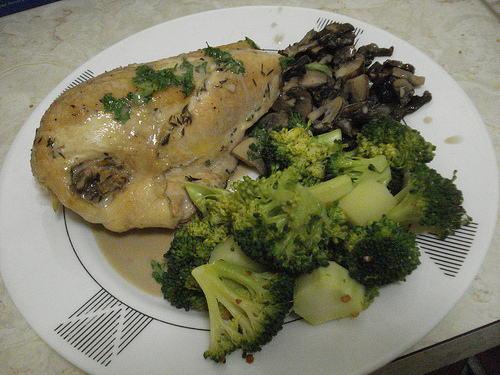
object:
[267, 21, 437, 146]
mushrooms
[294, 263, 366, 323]
stems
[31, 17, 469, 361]
dinner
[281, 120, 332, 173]
vegetables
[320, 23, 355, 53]
cut mushrooms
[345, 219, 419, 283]
floret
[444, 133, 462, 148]
drips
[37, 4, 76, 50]
vein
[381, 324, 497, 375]
table edge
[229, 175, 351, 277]
broccoli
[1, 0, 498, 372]
table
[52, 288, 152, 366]
design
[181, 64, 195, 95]
coriander leaves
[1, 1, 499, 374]
counter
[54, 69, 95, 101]
design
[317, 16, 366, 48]
design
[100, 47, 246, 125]
garnish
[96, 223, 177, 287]
gravy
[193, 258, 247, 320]
stem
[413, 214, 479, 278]
design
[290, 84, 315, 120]
mushrooms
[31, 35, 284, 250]
chicken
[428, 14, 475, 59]
counter top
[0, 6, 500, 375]
plate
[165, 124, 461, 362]
broccoli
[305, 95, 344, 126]
mushrooms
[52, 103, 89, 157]
skin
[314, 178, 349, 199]
stalks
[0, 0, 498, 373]
tabletop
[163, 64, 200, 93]
leaves